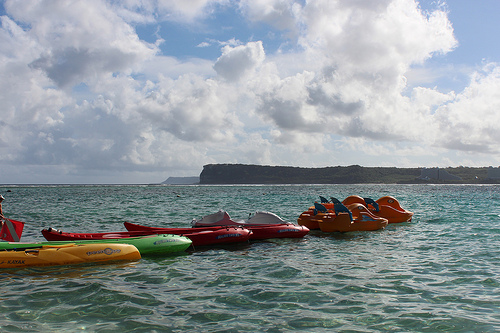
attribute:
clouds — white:
[14, 21, 214, 173]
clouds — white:
[0, 0, 497, 185]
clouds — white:
[25, 31, 219, 165]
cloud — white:
[213, 36, 266, 83]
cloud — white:
[41, 94, 166, 141]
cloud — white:
[438, 57, 498, 154]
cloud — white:
[161, 0, 215, 26]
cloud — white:
[229, 133, 271, 164]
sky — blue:
[0, 0, 497, 184]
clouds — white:
[275, 3, 497, 157]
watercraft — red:
[189, 208, 310, 238]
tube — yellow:
[0, 242, 142, 267]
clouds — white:
[201, 27, 277, 58]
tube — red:
[209, 200, 357, 264]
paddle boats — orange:
[293, 194, 415, 233]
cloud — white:
[303, 2, 458, 81]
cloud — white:
[434, 63, 497, 151]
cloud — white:
[3, 0, 159, 74]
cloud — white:
[1, 57, 70, 147]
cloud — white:
[131, 74, 238, 145]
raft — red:
[238, 203, 310, 245]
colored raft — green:
[141, 229, 193, 258]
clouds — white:
[178, 65, 333, 142]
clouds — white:
[299, 8, 442, 94]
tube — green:
[1, 233, 194, 257]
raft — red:
[34, 223, 259, 252]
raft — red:
[287, 201, 387, 233]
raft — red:
[325, 187, 414, 227]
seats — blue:
[321, 196, 350, 212]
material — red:
[5, 210, 21, 237]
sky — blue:
[77, 13, 426, 137]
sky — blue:
[144, 47, 425, 157]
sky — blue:
[106, 15, 394, 141]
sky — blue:
[54, 49, 424, 145]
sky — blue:
[80, 43, 407, 105]